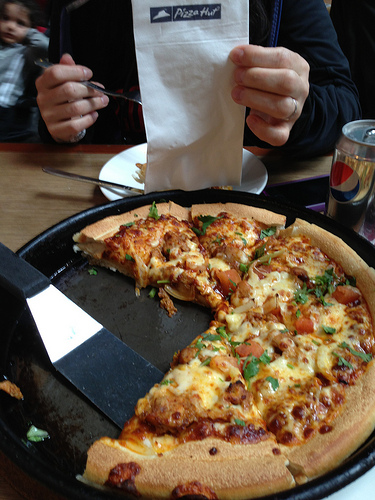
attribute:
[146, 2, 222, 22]
writing — black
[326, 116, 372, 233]
pepsi can — silver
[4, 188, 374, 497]
pizza —  with  slices missing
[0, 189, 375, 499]
serving dish — black, round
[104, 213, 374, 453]
cheese — yellow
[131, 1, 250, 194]
napkin — Pizza Hut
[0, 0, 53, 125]
kid — little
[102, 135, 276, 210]
plate — white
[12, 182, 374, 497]
pan — black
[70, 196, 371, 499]
pizza —  with 2 slices missing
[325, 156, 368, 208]
logo — Pepsi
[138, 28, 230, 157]
napkin — white, paper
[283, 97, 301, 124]
band — gold, thin, wedding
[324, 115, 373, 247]
can — soda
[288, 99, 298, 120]
ring — wedding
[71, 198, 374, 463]
pizza — cheesy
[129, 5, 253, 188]
receipt — white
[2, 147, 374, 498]
table — brown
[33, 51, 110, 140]
hand —  Person's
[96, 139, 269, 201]
plate — white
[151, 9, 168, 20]
logo —  Pizza Hut